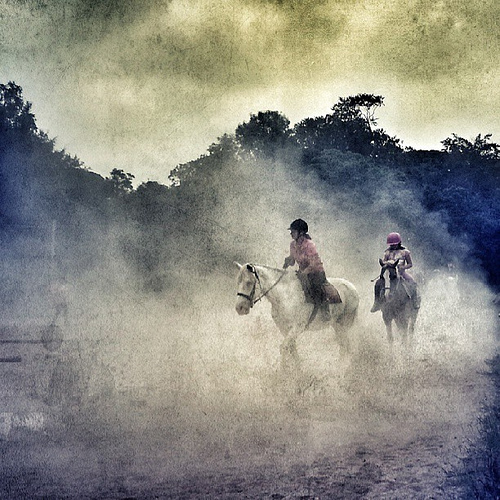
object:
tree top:
[169, 149, 227, 179]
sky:
[0, 0, 500, 188]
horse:
[234, 260, 360, 377]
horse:
[378, 257, 421, 350]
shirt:
[286, 234, 326, 273]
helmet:
[385, 232, 403, 244]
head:
[289, 217, 310, 241]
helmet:
[290, 217, 311, 235]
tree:
[330, 91, 385, 133]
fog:
[0, 135, 500, 493]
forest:
[0, 78, 500, 302]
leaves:
[248, 121, 258, 133]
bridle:
[232, 265, 290, 313]